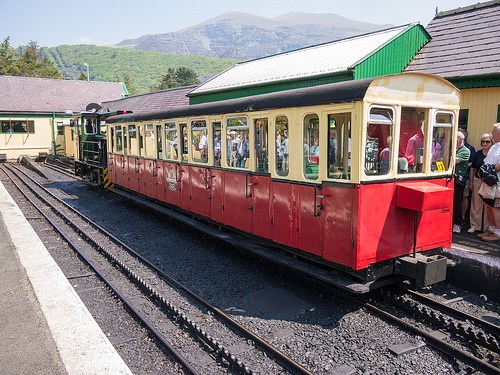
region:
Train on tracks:
[77, 65, 474, 303]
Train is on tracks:
[70, 58, 467, 301]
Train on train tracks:
[65, 65, 462, 300]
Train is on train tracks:
[65, 67, 467, 300]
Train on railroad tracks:
[68, 64, 468, 301]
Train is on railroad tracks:
[65, 65, 474, 307]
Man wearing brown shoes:
[472, 227, 497, 243]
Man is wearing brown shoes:
[478, 226, 498, 245]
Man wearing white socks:
[485, 219, 498, 238]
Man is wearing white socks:
[485, 221, 499, 240]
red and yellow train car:
[85, 66, 483, 290]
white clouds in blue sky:
[7, 18, 47, 43]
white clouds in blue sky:
[47, 16, 92, 54]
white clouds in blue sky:
[110, 8, 161, 38]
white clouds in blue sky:
[10, 1, 68, 42]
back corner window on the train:
[328, 108, 352, 180]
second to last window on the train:
[301, 108, 325, 180]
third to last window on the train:
[272, 112, 293, 178]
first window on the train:
[110, 126, 116, 153]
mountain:
[110, 7, 402, 60]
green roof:
[188, 20, 433, 104]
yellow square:
[435, 159, 448, 174]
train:
[67, 70, 470, 303]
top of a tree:
[155, 64, 205, 92]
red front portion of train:
[345, 169, 460, 291]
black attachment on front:
[411, 246, 452, 287]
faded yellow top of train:
[362, 72, 459, 184]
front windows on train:
[355, 109, 452, 176]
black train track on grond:
[424, 298, 486, 348]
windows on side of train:
[194, 116, 376, 180]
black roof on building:
[260, 35, 345, 85]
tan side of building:
[0, 116, 61, 163]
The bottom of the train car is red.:
[106, 153, 453, 268]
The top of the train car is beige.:
[106, 102, 458, 179]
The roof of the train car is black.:
[106, 78, 371, 124]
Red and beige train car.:
[106, 72, 462, 294]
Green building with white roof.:
[188, 22, 430, 104]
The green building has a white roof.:
[190, 22, 415, 92]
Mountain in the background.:
[113, 10, 395, 54]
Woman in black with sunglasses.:
[468, 132, 493, 234]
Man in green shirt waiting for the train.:
[456, 131, 468, 233]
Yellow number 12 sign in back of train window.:
[434, 161, 445, 170]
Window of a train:
[328, 109, 353, 184]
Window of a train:
[301, 113, 322, 182]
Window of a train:
[273, 115, 288, 177]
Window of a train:
[368, 107, 393, 177]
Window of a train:
[433, 111, 453, 172]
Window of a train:
[162, 122, 178, 158]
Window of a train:
[161, 118, 180, 160]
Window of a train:
[301, 113, 317, 188]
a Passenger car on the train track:
[102, 104, 469, 304]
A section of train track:
[77, 230, 163, 305]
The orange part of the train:
[102, 146, 459, 270]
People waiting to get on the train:
[459, 121, 499, 241]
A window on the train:
[298, 105, 327, 189]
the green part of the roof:
[347, 22, 431, 76]